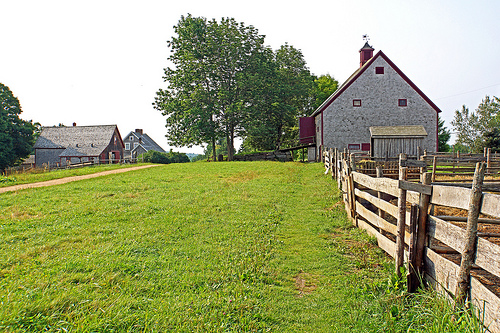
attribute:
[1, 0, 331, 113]
clouds — white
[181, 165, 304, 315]
grass — green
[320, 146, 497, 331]
fence — old, wood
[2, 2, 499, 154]
sky — blue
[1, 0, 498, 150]
cloud — white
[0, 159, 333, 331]
grass — lush, green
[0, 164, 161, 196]
pathway — dirt pathway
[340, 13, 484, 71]
clouds — white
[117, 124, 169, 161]
house — small, grey, in distance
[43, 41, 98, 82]
clouds — white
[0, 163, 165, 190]
pathway — dirt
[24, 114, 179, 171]
farm — building, in distance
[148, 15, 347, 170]
trees — large, stand, gently swaying in breeze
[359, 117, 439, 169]
shed — small, wooden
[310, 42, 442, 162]
barn — large, grey, burgundy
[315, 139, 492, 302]
fencing — wooden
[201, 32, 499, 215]
farm — country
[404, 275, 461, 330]
grass — tall, growing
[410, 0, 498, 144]
sky — blue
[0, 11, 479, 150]
sky — blue